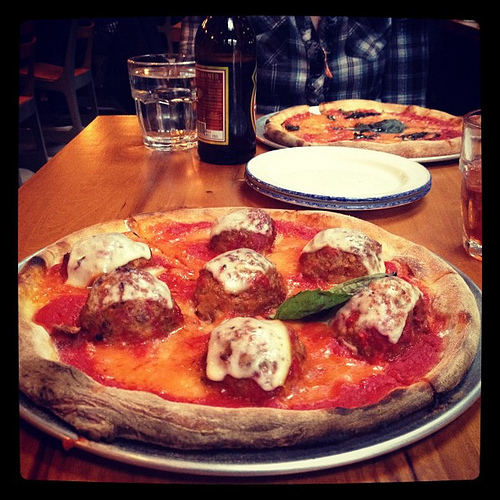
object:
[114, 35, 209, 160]
glass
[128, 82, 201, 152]
water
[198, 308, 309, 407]
meatball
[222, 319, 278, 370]
cheese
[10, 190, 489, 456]
pizza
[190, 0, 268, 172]
bottle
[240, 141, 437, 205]
plates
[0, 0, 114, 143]
chairs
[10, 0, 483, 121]
background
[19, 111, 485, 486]
table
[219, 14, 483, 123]
person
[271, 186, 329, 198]
edges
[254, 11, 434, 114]
shirt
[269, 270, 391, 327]
leaf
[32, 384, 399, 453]
crust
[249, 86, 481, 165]
plate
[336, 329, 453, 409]
tomato sauce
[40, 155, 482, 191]
middle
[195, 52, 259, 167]
beer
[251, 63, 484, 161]
pizzas